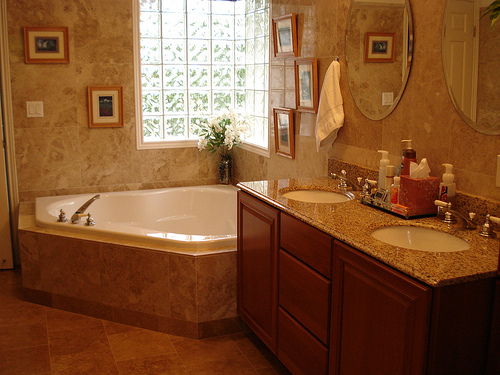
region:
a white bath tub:
[25, 160, 261, 255]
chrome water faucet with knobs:
[51, 188, 106, 229]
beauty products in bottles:
[372, 136, 460, 216]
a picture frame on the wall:
[23, 23, 75, 66]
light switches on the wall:
[25, 99, 45, 121]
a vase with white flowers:
[201, 110, 247, 186]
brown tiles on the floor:
[40, 314, 134, 369]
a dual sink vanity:
[251, 160, 481, 277]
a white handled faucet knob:
[430, 195, 454, 214]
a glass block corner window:
[136, 2, 279, 143]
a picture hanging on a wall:
[81, 66, 124, 149]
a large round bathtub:
[29, 172, 254, 247]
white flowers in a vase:
[194, 101, 249, 199]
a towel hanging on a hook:
[305, 52, 350, 158]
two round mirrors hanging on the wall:
[380, 10, 485, 126]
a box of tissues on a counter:
[394, 157, 449, 219]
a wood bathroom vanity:
[223, 213, 494, 373]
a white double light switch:
[18, 98, 45, 124]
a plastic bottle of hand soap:
[427, 156, 464, 230]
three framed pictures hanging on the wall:
[259, 15, 325, 170]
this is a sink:
[101, 190, 223, 230]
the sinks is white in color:
[145, 194, 205, 226]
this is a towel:
[314, 67, 341, 141]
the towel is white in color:
[316, 100, 331, 127]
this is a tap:
[76, 195, 115, 222]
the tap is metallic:
[48, 195, 105, 225]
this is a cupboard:
[252, 228, 324, 307]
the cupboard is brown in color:
[272, 226, 319, 269]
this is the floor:
[51, 333, 136, 373]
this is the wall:
[38, 81, 71, 172]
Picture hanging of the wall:
[265, 10, 306, 62]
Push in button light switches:
[21, 95, 46, 123]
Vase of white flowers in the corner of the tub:
[192, 108, 252, 186]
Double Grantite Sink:
[237, 148, 499, 308]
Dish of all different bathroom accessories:
[348, 133, 459, 223]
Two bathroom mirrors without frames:
[332, 1, 497, 146]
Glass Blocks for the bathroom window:
[135, 0, 269, 157]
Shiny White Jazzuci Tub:
[31, 182, 266, 258]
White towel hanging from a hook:
[302, 55, 356, 162]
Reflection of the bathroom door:
[394, 0, 486, 159]